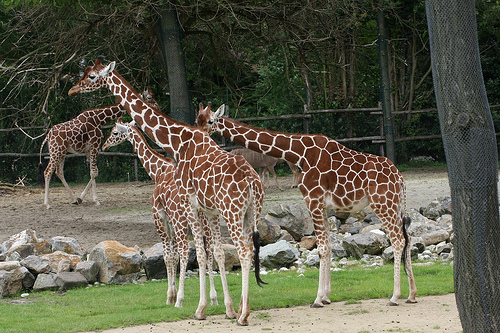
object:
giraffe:
[32, 87, 184, 209]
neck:
[229, 125, 302, 158]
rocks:
[94, 238, 149, 286]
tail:
[394, 219, 419, 279]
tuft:
[401, 215, 411, 227]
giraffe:
[67, 60, 263, 325]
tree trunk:
[428, 0, 498, 330]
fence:
[402, 69, 455, 168]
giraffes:
[184, 101, 424, 311]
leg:
[304, 197, 343, 310]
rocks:
[268, 238, 298, 267]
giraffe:
[189, 98, 419, 312]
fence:
[293, 71, 395, 147]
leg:
[369, 189, 409, 309]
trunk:
[421, 0, 500, 333]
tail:
[249, 224, 267, 285]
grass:
[0, 290, 53, 333]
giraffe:
[98, 113, 228, 310]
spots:
[200, 162, 232, 183]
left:
[0, 143, 14, 313]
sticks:
[383, 101, 399, 155]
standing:
[152, 206, 407, 333]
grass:
[59, 280, 174, 323]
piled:
[11, 227, 70, 298]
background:
[0, 85, 33, 186]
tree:
[127, 0, 156, 179]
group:
[184, 99, 416, 311]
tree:
[32, 97, 41, 185]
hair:
[251, 254, 271, 287]